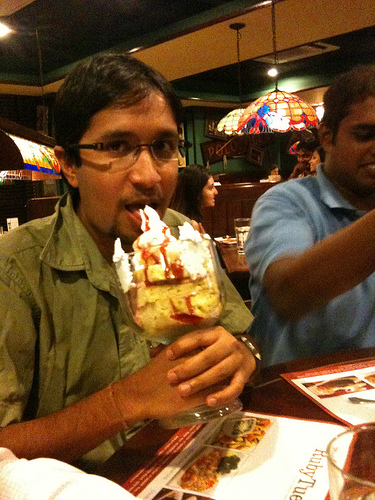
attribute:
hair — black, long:
[167, 160, 213, 222]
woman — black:
[176, 162, 222, 232]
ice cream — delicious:
[79, 197, 232, 341]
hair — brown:
[49, 48, 188, 213]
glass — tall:
[109, 250, 244, 428]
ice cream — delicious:
[112, 204, 225, 341]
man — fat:
[1, 54, 262, 462]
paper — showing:
[119, 408, 353, 499]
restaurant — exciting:
[3, 1, 374, 498]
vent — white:
[258, 42, 341, 67]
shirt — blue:
[245, 167, 373, 359]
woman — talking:
[175, 163, 217, 233]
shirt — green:
[0, 193, 251, 472]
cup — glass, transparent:
[319, 415, 374, 498]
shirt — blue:
[246, 162, 363, 370]